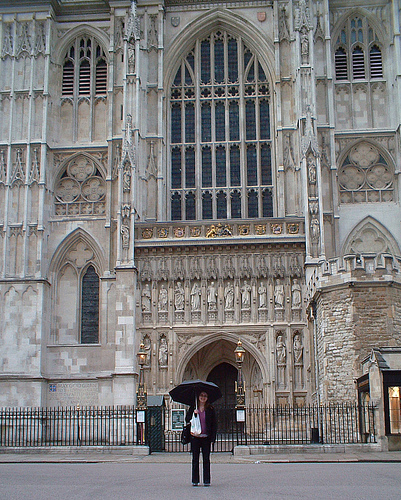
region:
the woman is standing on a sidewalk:
[168, 378, 222, 485]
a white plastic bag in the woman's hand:
[190, 408, 203, 435]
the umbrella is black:
[168, 380, 221, 402]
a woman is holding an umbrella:
[167, 379, 220, 438]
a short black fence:
[0, 406, 138, 443]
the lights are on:
[134, 343, 244, 367]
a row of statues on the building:
[142, 276, 302, 312]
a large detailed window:
[169, 27, 276, 218]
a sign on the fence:
[236, 408, 244, 422]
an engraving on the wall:
[46, 382, 98, 406]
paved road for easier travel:
[0, 463, 189, 499]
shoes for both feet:
[192, 480, 214, 486]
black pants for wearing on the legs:
[188, 436, 212, 485]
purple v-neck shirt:
[191, 410, 211, 439]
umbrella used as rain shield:
[169, 378, 220, 430]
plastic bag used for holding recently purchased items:
[189, 410, 202, 435]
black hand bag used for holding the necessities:
[180, 421, 192, 443]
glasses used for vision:
[198, 394, 206, 398]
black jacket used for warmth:
[207, 404, 217, 440]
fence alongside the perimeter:
[2, 401, 177, 449]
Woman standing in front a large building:
[183, 388, 219, 487]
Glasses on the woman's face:
[195, 390, 206, 398]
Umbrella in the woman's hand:
[168, 378, 220, 416]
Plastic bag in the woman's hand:
[189, 410, 201, 436]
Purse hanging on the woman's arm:
[180, 418, 192, 444]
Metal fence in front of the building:
[0, 400, 376, 447]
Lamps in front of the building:
[134, 334, 246, 442]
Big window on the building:
[164, 7, 280, 220]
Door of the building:
[207, 362, 245, 434]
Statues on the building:
[120, 26, 321, 366]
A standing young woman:
[169, 375, 221, 486]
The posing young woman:
[170, 375, 221, 485]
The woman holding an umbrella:
[170, 377, 230, 488]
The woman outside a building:
[0, 0, 400, 499]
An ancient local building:
[0, 0, 399, 447]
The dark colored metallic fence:
[0, 401, 374, 446]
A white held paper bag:
[190, 408, 200, 434]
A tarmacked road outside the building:
[0, 451, 397, 498]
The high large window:
[138, 10, 303, 238]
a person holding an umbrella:
[162, 376, 219, 440]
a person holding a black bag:
[179, 425, 196, 456]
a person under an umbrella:
[168, 376, 219, 417]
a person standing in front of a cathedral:
[169, 376, 229, 495]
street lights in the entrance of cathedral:
[128, 340, 270, 364]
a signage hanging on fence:
[166, 407, 196, 435]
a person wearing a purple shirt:
[197, 410, 217, 429]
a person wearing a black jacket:
[203, 407, 223, 441]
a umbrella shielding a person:
[166, 378, 222, 411]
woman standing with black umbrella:
[169, 380, 222, 485]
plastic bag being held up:
[189, 409, 201, 436]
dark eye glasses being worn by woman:
[199, 392, 207, 396]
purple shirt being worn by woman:
[196, 409, 206, 436]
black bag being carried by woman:
[181, 422, 191, 442]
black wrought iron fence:
[0, 401, 378, 455]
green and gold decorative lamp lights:
[136, 337, 244, 444]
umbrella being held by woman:
[157, 370, 239, 492]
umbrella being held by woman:
[157, 362, 254, 487]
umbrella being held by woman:
[150, 370, 240, 487]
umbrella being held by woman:
[165, 370, 242, 485]